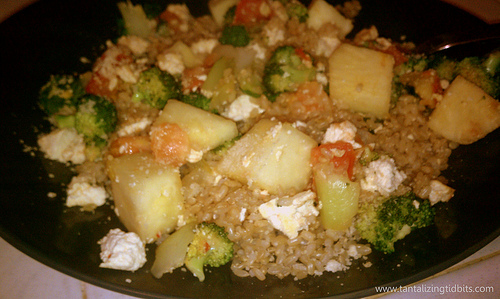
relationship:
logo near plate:
[368, 279, 497, 295] [1, 1, 494, 298]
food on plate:
[38, 1, 478, 273] [1, 1, 494, 298]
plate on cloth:
[1, 1, 494, 298] [1, 233, 497, 293]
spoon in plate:
[382, 13, 500, 81] [1, 1, 494, 298]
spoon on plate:
[382, 13, 500, 81] [1, 1, 494, 298]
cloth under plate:
[1, 233, 497, 293] [1, 1, 494, 298]